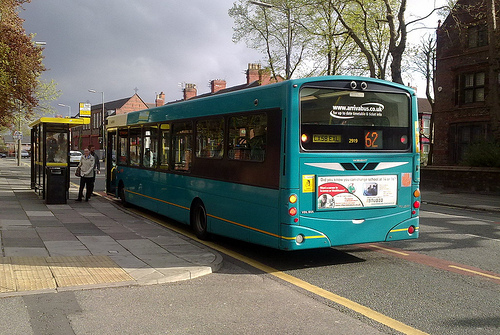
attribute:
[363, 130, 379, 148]
62 — showing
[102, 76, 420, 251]
bus — teal colored, long, turquoise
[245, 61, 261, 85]
chimney — brick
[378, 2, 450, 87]
tree — tall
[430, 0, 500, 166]
building — old, red brick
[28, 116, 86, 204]
bus stop — yellow, black, shelter, here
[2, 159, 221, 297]
sidewalk — concrete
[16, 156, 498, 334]
street — grey, paved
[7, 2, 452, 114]
sky — dark, grey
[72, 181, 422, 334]
stripe — yellow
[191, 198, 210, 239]
tire — black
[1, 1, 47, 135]
leaves — brown, green